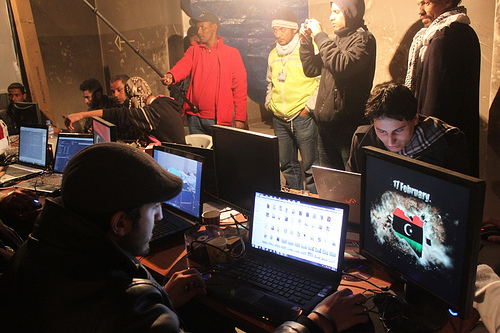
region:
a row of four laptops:
[8, 121, 362, 330]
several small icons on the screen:
[261, 200, 338, 260]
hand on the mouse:
[309, 282, 368, 331]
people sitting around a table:
[1, 55, 494, 327]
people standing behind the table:
[149, 0, 497, 185]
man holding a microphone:
[83, 4, 258, 149]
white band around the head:
[266, 15, 301, 32]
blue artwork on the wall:
[186, 0, 323, 103]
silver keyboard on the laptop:
[1, 159, 41, 186]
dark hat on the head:
[57, 137, 192, 223]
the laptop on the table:
[211, 185, 347, 319]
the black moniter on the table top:
[350, 141, 485, 313]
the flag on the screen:
[381, 200, 438, 253]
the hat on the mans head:
[51, 139, 186, 206]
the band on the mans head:
[266, 17, 298, 31]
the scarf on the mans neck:
[406, 11, 481, 101]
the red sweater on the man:
[169, 36, 251, 123]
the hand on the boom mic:
[158, 63, 175, 93]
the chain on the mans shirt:
[270, 51, 295, 88]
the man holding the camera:
[300, 2, 371, 171]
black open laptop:
[197, 175, 353, 325]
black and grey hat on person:
[263, 5, 305, 36]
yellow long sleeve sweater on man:
[251, 40, 321, 119]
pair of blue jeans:
[263, 111, 328, 194]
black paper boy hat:
[53, 135, 188, 219]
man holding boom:
[81, 0, 252, 132]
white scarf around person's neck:
[400, 5, 476, 97]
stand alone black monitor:
[350, 143, 492, 331]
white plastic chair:
[178, 127, 217, 154]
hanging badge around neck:
[273, 55, 290, 87]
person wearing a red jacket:
[158, 11, 248, 141]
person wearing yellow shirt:
[260, 5, 325, 192]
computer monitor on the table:
[343, 137, 495, 311]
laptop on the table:
[211, 182, 358, 321]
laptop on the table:
[122, 140, 214, 251]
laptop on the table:
[22, 128, 99, 204]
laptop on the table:
[0, 119, 50, 186]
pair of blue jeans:
[274, 110, 320, 193]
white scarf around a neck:
[400, 2, 473, 103]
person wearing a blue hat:
[155, 8, 254, 138]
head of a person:
[64, 143, 189, 258]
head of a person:
[367, 88, 419, 165]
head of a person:
[109, 75, 134, 105]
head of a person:
[76, 77, 104, 104]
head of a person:
[253, 13, 306, 48]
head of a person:
[187, 11, 232, 40]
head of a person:
[416, 3, 458, 30]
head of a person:
[4, 75, 35, 100]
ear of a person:
[208, 24, 215, 31]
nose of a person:
[194, 23, 204, 33]